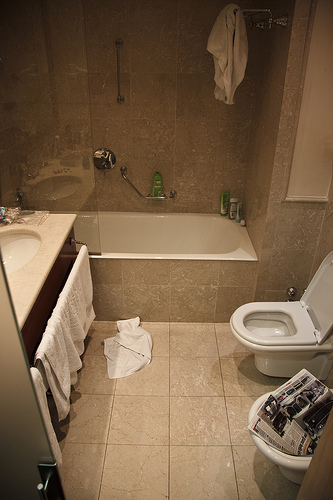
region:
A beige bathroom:
[22, 134, 324, 432]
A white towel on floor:
[96, 318, 150, 381]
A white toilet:
[222, 269, 302, 361]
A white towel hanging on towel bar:
[52, 271, 92, 384]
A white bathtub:
[84, 205, 239, 260]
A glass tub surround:
[11, 10, 126, 233]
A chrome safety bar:
[105, 30, 137, 111]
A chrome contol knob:
[95, 143, 116, 176]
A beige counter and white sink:
[3, 205, 65, 286]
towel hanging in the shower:
[204, 5, 263, 115]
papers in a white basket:
[235, 364, 331, 491]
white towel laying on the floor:
[93, 314, 168, 386]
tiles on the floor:
[44, 306, 320, 498]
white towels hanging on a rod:
[23, 238, 98, 430]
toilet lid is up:
[296, 251, 332, 336]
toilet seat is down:
[227, 300, 310, 350]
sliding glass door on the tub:
[0, 2, 151, 267]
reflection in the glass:
[24, 150, 100, 212]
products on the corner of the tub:
[203, 186, 247, 226]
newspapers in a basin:
[261, 388, 319, 439]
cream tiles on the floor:
[91, 389, 246, 499]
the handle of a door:
[35, 468, 58, 498]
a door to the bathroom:
[5, 323, 38, 489]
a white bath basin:
[82, 215, 244, 262]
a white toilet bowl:
[241, 342, 312, 375]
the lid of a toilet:
[315, 270, 330, 319]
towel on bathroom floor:
[98, 315, 158, 379]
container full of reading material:
[246, 370, 332, 477]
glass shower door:
[4, 55, 110, 253]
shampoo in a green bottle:
[148, 167, 165, 200]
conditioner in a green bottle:
[216, 185, 229, 222]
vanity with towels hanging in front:
[2, 217, 100, 433]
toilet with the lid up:
[230, 244, 329, 380]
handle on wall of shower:
[109, 31, 137, 107]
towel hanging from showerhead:
[207, 4, 249, 112]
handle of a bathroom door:
[29, 456, 70, 497]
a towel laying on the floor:
[107, 308, 155, 438]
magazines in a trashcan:
[237, 376, 315, 458]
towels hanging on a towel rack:
[27, 314, 60, 402]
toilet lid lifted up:
[309, 249, 329, 328]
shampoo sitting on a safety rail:
[148, 170, 176, 207]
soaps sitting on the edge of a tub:
[213, 191, 257, 227]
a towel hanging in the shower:
[218, 6, 252, 112]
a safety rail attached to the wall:
[103, 49, 138, 120]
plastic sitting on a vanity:
[1, 205, 53, 237]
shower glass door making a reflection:
[2, 123, 90, 201]